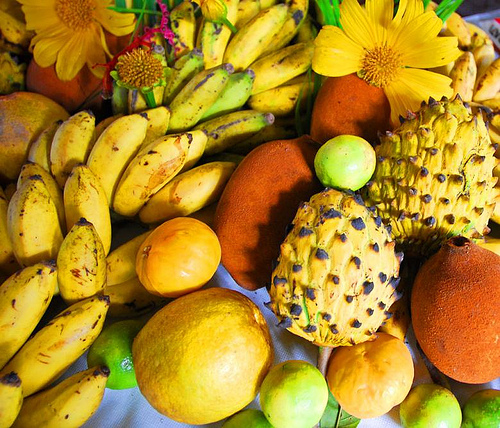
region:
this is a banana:
[12, 296, 112, 390]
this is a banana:
[56, 216, 103, 297]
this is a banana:
[3, 171, 56, 266]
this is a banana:
[117, 130, 197, 213]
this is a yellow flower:
[336, 3, 461, 100]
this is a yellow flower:
[22, 5, 102, 67]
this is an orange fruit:
[410, 234, 497, 387]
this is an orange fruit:
[216, 131, 314, 291]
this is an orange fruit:
[314, 72, 386, 142]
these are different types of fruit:
[5, 1, 497, 426]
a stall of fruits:
[55, 14, 328, 418]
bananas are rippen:
[21, 194, 126, 294]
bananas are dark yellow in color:
[1, 165, 116, 347]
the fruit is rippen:
[301, 224, 380, 329]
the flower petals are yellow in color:
[343, 9, 456, 100]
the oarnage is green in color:
[272, 363, 340, 426]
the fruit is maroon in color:
[434, 229, 497, 371]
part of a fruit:
[217, 376, 239, 401]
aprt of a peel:
[210, 378, 230, 395]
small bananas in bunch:
[37, 133, 169, 424]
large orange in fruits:
[147, 285, 277, 417]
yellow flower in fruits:
[326, 23, 448, 146]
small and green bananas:
[97, 31, 249, 136]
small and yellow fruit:
[265, 349, 330, 415]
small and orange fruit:
[140, 231, 225, 276]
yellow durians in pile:
[272, 93, 468, 342]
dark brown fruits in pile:
[187, 85, 397, 316]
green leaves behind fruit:
[294, 365, 359, 427]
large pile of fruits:
[13, 14, 485, 426]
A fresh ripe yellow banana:
[4, 280, 113, 427]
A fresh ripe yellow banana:
[8, 168, 146, 290]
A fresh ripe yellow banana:
[61, 107, 222, 219]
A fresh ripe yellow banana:
[115, 30, 250, 138]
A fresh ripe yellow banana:
[197, 10, 344, 74]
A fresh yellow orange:
[132, 203, 217, 298]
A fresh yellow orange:
[269, 355, 321, 415]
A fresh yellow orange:
[337, 328, 404, 411]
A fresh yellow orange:
[142, 300, 257, 401]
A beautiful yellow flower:
[322, 0, 425, 121]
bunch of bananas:
[12, 109, 221, 300]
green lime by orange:
[262, 313, 421, 425]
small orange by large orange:
[122, 216, 272, 421]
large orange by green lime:
[129, 285, 327, 426]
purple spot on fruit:
[348, 214, 368, 240]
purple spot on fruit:
[433, 168, 447, 184]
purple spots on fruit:
[398, 144, 447, 231]